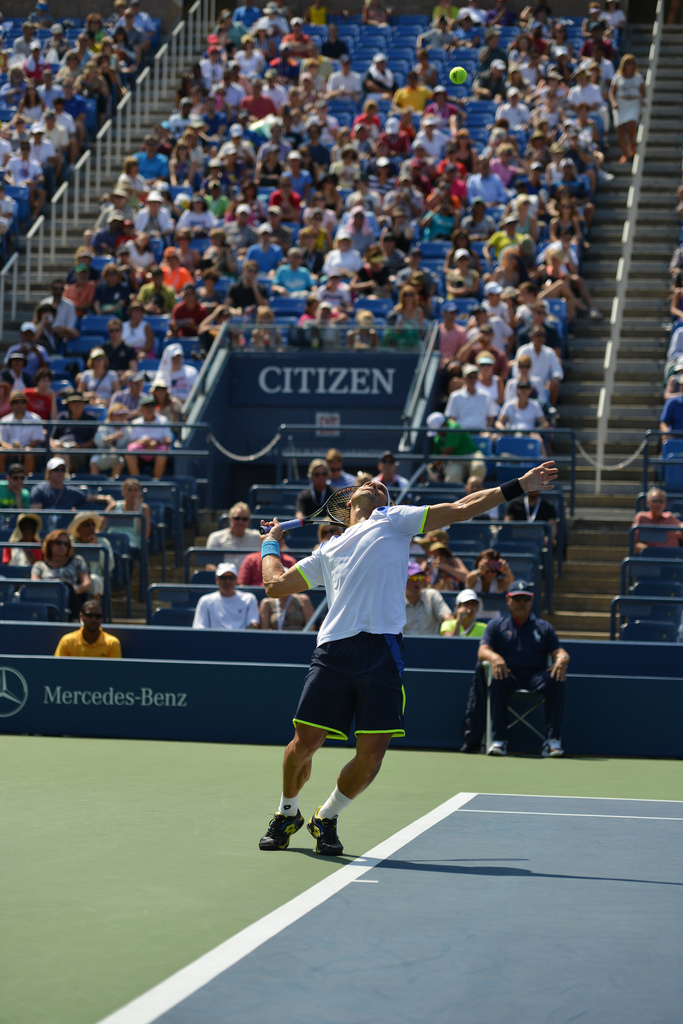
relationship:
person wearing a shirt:
[36, 584, 112, 654] [36, 584, 112, 654]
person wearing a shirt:
[173, 539, 274, 636] [173, 539, 274, 636]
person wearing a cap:
[173, 539, 274, 636] [173, 539, 274, 636]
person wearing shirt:
[156, 246, 185, 290] [138, 238, 194, 312]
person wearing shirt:
[71, 521, 147, 573] [71, 521, 147, 573]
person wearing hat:
[71, 521, 147, 573] [71, 521, 147, 573]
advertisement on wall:
[36, 654, 209, 735] [36, 654, 209, 735]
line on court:
[126, 787, 660, 1013] [126, 787, 660, 1013]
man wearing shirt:
[255, 469, 508, 691] [255, 469, 508, 691]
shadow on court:
[318, 821, 677, 911] [40, 406, 619, 1016]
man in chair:
[475, 585, 596, 766] [462, 654, 565, 775]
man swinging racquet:
[255, 469, 455, 804] [254, 461, 565, 856]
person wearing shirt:
[52, 584, 124, 653] [53, 597, 115, 658]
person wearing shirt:
[173, 539, 274, 637] [194, 559, 256, 629]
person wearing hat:
[173, 539, 274, 637] [213, 552, 239, 580]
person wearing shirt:
[155, 245, 184, 289] [160, 247, 192, 290]